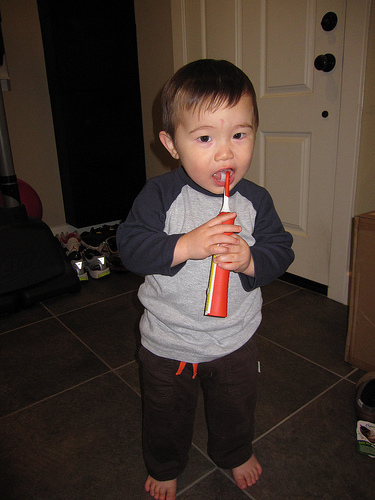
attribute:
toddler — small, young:
[117, 61, 297, 497]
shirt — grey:
[116, 173, 294, 366]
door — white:
[172, 0, 356, 303]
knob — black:
[316, 51, 332, 72]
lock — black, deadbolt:
[320, 8, 338, 33]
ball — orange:
[14, 176, 46, 221]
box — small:
[347, 215, 374, 378]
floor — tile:
[0, 280, 374, 500]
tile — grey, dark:
[116, 322, 341, 472]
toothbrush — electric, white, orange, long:
[205, 170, 237, 321]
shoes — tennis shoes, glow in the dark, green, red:
[55, 222, 120, 283]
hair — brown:
[160, 58, 264, 133]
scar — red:
[219, 121, 227, 133]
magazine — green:
[355, 421, 373, 461]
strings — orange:
[175, 362, 202, 379]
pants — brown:
[140, 338, 258, 480]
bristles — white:
[219, 173, 227, 183]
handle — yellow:
[205, 211, 237, 322]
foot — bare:
[232, 453, 266, 493]